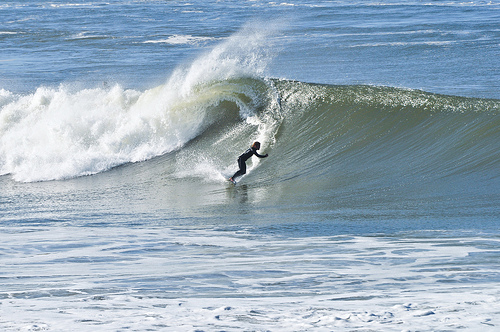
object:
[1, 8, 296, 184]
foam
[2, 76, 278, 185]
white cap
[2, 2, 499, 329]
ocean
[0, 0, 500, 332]
ground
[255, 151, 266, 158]
arms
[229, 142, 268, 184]
person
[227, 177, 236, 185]
surfboard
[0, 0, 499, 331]
ocean water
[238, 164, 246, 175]
bent knees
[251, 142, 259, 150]
caps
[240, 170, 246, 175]
knees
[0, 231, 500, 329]
ripples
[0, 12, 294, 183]
splashing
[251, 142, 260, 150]
head